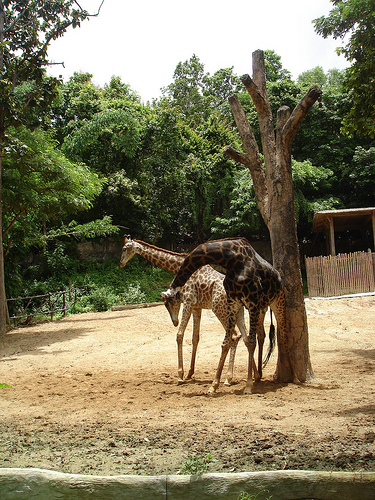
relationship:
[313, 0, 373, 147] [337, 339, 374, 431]
trees have shadows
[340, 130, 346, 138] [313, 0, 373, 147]
leaves on trees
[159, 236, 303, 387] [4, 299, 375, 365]
giraffes standing in sand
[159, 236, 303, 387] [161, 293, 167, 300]
giraffes have horns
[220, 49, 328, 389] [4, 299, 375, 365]
tree growing out of sand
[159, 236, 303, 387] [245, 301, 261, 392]
giraffes have legs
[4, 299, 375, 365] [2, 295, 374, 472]
sand on ground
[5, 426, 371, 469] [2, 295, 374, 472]
dirt on ground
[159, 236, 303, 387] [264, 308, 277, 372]
giraffes have tail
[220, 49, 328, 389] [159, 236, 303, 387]
tree next to giraffes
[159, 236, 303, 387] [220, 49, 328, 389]
giraffes next to tree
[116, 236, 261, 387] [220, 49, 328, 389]
giraffe next to tree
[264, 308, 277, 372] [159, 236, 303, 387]
tail on giraffes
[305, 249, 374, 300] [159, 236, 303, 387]
fence behind giraffes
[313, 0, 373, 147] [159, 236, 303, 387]
trees behind giraffes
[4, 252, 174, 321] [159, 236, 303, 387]
bushes behind giraffes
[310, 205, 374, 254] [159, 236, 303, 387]
hut behind giraffes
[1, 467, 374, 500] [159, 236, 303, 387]
wall in front of giraffes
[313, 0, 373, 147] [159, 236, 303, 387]
trees around giraffes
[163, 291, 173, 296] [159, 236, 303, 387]
ears on giraffes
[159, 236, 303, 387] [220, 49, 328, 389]
giraffes near tree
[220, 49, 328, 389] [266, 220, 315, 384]
tree has trunk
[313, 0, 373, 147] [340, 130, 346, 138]
trees with leaves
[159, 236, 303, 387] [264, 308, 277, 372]
giraffes has tail